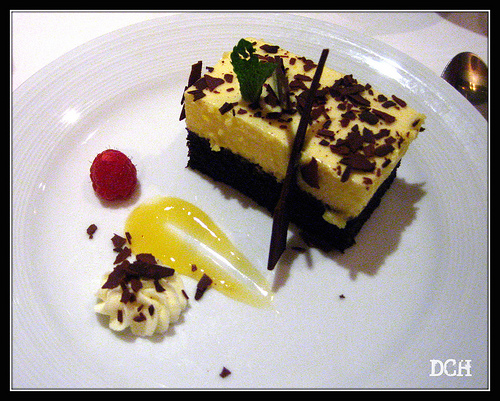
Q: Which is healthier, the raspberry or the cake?
A: The raspberry is healthier than the cake.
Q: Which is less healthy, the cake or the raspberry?
A: The cake is less healthy than the raspberry.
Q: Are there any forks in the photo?
A: No, there are no forks.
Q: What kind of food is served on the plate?
A: The food is a dessert.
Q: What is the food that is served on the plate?
A: The food is a dessert.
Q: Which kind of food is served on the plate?
A: The food is a dessert.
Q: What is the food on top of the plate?
A: The food is a dessert.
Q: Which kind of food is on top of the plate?
A: The food is a dessert.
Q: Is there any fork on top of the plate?
A: No, there is a dessert on top of the plate.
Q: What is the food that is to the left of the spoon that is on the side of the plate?
A: The food is a dessert.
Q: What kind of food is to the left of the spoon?
A: The food is a dessert.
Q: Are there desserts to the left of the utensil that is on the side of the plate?
A: Yes, there is a dessert to the left of the spoon.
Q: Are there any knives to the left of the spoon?
A: No, there is a dessert to the left of the spoon.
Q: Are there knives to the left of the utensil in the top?
A: No, there is a dessert to the left of the spoon.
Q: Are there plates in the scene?
A: Yes, there is a plate.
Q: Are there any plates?
A: Yes, there is a plate.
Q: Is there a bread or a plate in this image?
A: Yes, there is a plate.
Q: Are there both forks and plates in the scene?
A: No, there is a plate but no forks.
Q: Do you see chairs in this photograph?
A: No, there are no chairs.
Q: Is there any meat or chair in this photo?
A: No, there are no chairs or meat.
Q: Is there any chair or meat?
A: No, there are no chairs or meat.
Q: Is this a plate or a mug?
A: This is a plate.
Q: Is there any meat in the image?
A: No, there is no meat.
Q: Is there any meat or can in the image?
A: No, there are no meat or cans.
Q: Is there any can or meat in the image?
A: No, there are no meat or cans.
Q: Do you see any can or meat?
A: No, there are no meat or cans.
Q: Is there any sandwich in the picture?
A: No, there are no sandwiches.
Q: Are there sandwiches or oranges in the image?
A: No, there are no sandwiches or oranges.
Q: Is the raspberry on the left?
A: Yes, the raspberry is on the left of the image.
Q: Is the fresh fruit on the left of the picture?
A: Yes, the raspberry is on the left of the image.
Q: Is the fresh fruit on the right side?
A: No, the raspberry is on the left of the image.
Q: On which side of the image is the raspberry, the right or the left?
A: The raspberry is on the left of the image.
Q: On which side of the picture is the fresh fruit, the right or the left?
A: The raspberry is on the left of the image.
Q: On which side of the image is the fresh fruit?
A: The raspberry is on the left of the image.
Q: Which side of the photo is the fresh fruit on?
A: The raspberry is on the left of the image.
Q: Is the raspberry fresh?
A: Yes, the raspberry is fresh.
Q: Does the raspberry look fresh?
A: Yes, the raspberry is fresh.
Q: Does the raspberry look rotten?
A: No, the raspberry is fresh.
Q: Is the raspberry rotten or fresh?
A: The raspberry is fresh.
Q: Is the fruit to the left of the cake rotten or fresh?
A: The raspberry is fresh.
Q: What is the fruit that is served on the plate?
A: The fruit is a raspberry.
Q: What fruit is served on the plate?
A: The fruit is a raspberry.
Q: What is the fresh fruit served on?
A: The raspberry is served on a plate.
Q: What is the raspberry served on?
A: The raspberry is served on a plate.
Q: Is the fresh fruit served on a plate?
A: Yes, the raspberry is served on a plate.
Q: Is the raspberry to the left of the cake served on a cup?
A: No, the raspberry is served on a plate.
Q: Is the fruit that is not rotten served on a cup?
A: No, the raspberry is served on a plate.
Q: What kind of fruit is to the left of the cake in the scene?
A: The fruit is a raspberry.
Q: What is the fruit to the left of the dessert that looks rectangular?
A: The fruit is a raspberry.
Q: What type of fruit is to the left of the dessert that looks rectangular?
A: The fruit is a raspberry.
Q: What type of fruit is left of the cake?
A: The fruit is a raspberry.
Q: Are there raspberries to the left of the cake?
A: Yes, there is a raspberry to the left of the cake.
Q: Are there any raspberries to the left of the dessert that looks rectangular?
A: Yes, there is a raspberry to the left of the cake.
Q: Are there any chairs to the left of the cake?
A: No, there is a raspberry to the left of the cake.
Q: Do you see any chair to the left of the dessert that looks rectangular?
A: No, there is a raspberry to the left of the cake.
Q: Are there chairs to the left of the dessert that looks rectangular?
A: No, there is a raspberry to the left of the cake.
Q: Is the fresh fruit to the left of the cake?
A: Yes, the raspberry is to the left of the cake.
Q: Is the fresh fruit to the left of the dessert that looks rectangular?
A: Yes, the raspberry is to the left of the cake.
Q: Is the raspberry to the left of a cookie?
A: No, the raspberry is to the left of the cake.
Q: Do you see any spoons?
A: Yes, there is a spoon.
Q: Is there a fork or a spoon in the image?
A: Yes, there is a spoon.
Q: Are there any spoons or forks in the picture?
A: Yes, there is a spoon.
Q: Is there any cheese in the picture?
A: No, there is no cheese.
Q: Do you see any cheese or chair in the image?
A: No, there are no cheese or chairs.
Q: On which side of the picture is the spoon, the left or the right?
A: The spoon is on the right of the image.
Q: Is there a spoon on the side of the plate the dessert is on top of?
A: Yes, there is a spoon on the side of the plate.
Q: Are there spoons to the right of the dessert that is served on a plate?
A: Yes, there is a spoon to the right of the dessert.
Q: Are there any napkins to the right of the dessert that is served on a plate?
A: No, there is a spoon to the right of the dessert.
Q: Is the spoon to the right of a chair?
A: No, the spoon is to the right of the dessert.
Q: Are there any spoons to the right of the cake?
A: Yes, there is a spoon to the right of the cake.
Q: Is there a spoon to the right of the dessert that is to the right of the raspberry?
A: Yes, there is a spoon to the right of the cake.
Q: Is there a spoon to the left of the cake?
A: No, the spoon is to the right of the cake.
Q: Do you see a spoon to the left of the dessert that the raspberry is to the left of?
A: No, the spoon is to the right of the cake.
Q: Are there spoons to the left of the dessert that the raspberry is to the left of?
A: No, the spoon is to the right of the cake.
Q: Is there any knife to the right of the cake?
A: No, there is a spoon to the right of the cake.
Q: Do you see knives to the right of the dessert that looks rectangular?
A: No, there is a spoon to the right of the cake.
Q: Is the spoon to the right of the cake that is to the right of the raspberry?
A: Yes, the spoon is to the right of the cake.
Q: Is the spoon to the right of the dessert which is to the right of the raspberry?
A: Yes, the spoon is to the right of the cake.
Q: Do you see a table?
A: Yes, there is a table.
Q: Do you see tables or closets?
A: Yes, there is a table.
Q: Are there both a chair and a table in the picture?
A: No, there is a table but no chairs.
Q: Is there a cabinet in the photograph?
A: No, there are no cabinets.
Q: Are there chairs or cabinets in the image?
A: No, there are no cabinets or chairs.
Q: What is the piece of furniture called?
A: The piece of furniture is a table.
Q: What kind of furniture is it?
A: The piece of furniture is a table.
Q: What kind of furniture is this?
A: This is a table.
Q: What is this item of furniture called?
A: This is a table.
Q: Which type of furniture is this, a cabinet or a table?
A: This is a table.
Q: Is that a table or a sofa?
A: That is a table.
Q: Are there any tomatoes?
A: No, there are no tomatoes.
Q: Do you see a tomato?
A: No, there are no tomatoes.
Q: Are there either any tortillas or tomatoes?
A: No, there are no tomatoes or tortillas.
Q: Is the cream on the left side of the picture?
A: Yes, the cream is on the left of the image.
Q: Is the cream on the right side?
A: No, the cream is on the left of the image.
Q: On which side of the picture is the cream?
A: The cream is on the left of the image.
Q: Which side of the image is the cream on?
A: The cream is on the left of the image.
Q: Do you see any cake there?
A: Yes, there is a cake.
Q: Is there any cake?
A: Yes, there is a cake.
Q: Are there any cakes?
A: Yes, there is a cake.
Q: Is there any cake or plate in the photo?
A: Yes, there is a cake.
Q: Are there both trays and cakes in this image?
A: No, there is a cake but no trays.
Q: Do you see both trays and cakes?
A: No, there is a cake but no trays.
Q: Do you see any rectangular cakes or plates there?
A: Yes, there is a rectangular cake.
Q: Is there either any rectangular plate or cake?
A: Yes, there is a rectangular cake.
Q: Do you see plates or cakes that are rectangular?
A: Yes, the cake is rectangular.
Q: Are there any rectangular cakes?
A: Yes, there is a rectangular cake.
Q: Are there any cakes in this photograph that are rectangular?
A: Yes, there is a cake that is rectangular.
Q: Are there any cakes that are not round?
A: Yes, there is a rectangular cake.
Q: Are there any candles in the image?
A: No, there are no candles.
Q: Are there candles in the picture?
A: No, there are no candles.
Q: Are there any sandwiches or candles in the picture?
A: No, there are no candles or sandwiches.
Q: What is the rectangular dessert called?
A: The dessert is a cake.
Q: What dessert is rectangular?
A: The dessert is a cake.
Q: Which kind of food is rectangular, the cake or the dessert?
A: The cake is rectangular.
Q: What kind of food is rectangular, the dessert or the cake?
A: The cake is rectangular.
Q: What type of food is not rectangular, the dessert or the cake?
A: The dessert is not rectangular.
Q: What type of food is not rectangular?
A: The food is a dessert.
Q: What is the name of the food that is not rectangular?
A: The food is a dessert.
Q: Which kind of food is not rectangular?
A: The food is a dessert.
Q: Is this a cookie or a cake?
A: This is a cake.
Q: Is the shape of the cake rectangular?
A: Yes, the cake is rectangular.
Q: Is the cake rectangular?
A: Yes, the cake is rectangular.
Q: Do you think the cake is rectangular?
A: Yes, the cake is rectangular.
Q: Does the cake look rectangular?
A: Yes, the cake is rectangular.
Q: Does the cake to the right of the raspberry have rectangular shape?
A: Yes, the cake is rectangular.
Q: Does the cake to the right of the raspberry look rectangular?
A: Yes, the cake is rectangular.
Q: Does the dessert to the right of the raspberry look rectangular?
A: Yes, the cake is rectangular.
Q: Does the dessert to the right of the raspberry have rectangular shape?
A: Yes, the cake is rectangular.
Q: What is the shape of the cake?
A: The cake is rectangular.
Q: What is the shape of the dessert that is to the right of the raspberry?
A: The cake is rectangular.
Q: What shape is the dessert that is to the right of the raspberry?
A: The cake is rectangular.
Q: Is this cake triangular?
A: No, the cake is rectangular.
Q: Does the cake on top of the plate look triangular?
A: No, the cake is rectangular.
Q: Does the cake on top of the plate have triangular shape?
A: No, the cake is rectangular.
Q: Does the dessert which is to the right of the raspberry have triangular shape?
A: No, the cake is rectangular.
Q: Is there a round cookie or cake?
A: No, there is a cake but it is rectangular.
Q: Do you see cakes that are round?
A: No, there is a cake but it is rectangular.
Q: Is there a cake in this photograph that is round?
A: No, there is a cake but it is rectangular.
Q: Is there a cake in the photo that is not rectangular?
A: No, there is a cake but it is rectangular.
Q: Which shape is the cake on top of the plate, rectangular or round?
A: The cake is rectangular.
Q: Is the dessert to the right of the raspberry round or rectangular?
A: The cake is rectangular.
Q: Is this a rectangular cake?
A: Yes, this is a rectangular cake.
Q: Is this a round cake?
A: No, this is a rectangular cake.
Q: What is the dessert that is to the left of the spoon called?
A: The dessert is a cake.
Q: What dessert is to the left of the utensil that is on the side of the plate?
A: The dessert is a cake.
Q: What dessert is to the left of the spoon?
A: The dessert is a cake.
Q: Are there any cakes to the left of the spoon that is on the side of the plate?
A: Yes, there is a cake to the left of the spoon.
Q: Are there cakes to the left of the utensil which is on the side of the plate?
A: Yes, there is a cake to the left of the spoon.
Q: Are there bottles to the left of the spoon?
A: No, there is a cake to the left of the spoon.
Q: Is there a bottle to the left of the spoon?
A: No, there is a cake to the left of the spoon.